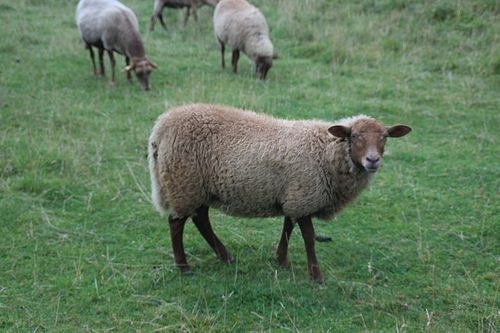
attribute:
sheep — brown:
[134, 94, 406, 284]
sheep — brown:
[143, 101, 412, 276]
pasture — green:
[9, 4, 484, 324]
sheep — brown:
[75, 2, 167, 92]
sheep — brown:
[212, 2, 282, 81]